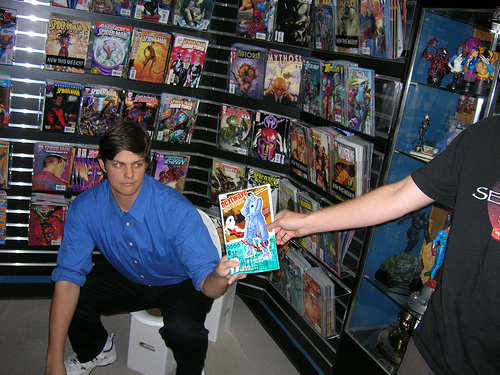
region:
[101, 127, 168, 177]
Person has brown hair.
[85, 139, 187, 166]
Person has short hair.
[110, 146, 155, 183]
Person has red eyes.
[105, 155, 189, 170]
Person has brown eyebrows.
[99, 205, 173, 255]
Person is wearing blue shirt.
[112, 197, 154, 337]
White buttons on shirt.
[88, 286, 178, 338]
Person wearing dark pants.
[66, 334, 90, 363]
Person wearing white tennis shoes.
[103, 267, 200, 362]
Person sitting on white object.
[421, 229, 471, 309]
Person wearing black t-shirt.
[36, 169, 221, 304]
a blue button down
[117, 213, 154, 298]
small white shirt buttons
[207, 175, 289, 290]
an asian comic book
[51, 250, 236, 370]
these are black pants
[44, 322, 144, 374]
this is a shoe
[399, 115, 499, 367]
this is a shirt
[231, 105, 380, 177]
these are comic books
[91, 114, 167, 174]
this is the hair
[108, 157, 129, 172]
this is the right eye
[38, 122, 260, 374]
this is a person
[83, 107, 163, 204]
a boy with brown hair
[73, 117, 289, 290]
a boy holding a magazine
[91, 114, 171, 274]
a boy wearing a blue shirt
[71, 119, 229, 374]
a man wearing black pants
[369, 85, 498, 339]
a person wearing a black shirt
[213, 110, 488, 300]
a person reaching for a magazine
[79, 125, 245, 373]
a man sitting on a toilet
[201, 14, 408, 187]
racks of comic books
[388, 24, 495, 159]
figurines sitting on a shelf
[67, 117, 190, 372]
a boy wearing white tennis shoes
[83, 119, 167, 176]
The man has dark hair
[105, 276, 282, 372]
The man is on a toilet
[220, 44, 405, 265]
The magazines are on display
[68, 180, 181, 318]
The man has buttons on his shirt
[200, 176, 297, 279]
The men are holding a comic book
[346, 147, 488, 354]
The action figures are on display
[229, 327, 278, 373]
The floor is light colored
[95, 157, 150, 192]
The man's eyes are open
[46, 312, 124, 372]
The man has sneakers on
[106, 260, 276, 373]
The man's pants are dark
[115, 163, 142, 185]
face of a man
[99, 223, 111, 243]
part of a shirt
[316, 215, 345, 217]
hand of a man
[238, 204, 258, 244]
front of a book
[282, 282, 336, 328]
part of a shelf